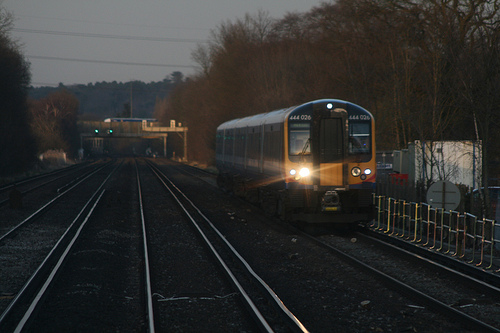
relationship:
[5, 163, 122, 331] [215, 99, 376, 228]
track without train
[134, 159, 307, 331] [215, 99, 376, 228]
track without train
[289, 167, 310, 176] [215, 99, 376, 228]
light on train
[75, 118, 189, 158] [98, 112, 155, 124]
bridge with vehicle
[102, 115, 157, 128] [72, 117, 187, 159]
vehicle on overpass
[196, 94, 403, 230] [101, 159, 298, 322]
train going on tracks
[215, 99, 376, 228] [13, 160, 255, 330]
train on tracks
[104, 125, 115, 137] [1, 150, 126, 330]
light over track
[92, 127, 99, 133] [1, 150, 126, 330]
light over track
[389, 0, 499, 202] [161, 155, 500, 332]
tree next to railroad tracks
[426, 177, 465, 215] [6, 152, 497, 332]
sign on tracks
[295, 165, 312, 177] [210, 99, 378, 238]
light on train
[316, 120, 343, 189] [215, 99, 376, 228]
door on train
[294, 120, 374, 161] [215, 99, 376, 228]
windows on train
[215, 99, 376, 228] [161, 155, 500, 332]
train on railroad tracks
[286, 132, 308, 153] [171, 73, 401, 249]
window front train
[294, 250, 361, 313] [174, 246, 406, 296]
rocks on track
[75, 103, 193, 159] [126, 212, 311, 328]
bridge over tracks